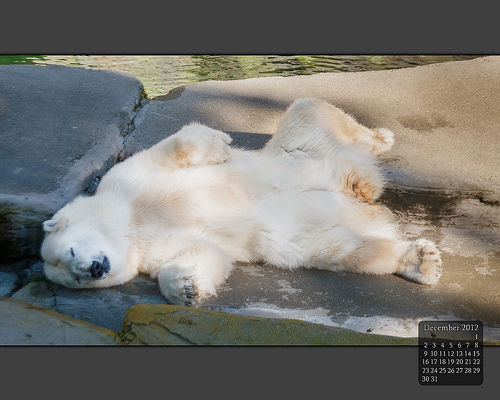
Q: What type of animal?
A: Polar bear.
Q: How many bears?
A: One.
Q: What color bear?
A: White.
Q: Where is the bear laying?
A: Concrete.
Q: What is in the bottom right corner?
A: Calendar.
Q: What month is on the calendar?
A: December.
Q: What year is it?
A: 2012.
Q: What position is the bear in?
A: On its back.